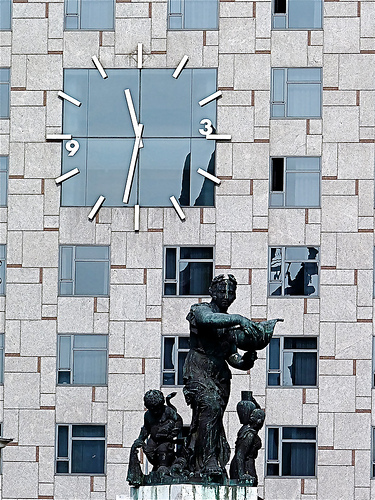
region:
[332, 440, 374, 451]
hotel catalonia, barcelona plaza, plaza espana, barcelona, spain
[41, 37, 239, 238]
the modern clock of the abovenoted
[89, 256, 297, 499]
statue is part of a fountain, & was designed by catalan architect, josep maria jujol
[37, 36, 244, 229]
clock is attached to a fancy hotel suite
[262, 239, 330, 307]
reflection of the statue in the mirrored windows of the fancy modernist hotel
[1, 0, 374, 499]
hotel is much MUCH larger than this, this is only a small detail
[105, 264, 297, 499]
tiny detail of an ENORMOUS almost crazily postmodern rococo fountain & statue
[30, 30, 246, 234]
clock is INCREDIBLY LARGE as well, 10'x10', easy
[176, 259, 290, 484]
woman with bowl needs to spend some time away from low flying birds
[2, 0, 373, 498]
the mosaicized walls of this hotel, in toto, continue for at least a block, more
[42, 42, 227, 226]
the fancy clock on the wall of the building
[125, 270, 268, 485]
the statue on top of the tower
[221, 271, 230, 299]
the white stain on the statue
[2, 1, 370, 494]
the building that the clock is attached too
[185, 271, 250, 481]
the part of the statue that looks like a woman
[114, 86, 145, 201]
the hands on the clock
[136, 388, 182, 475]
the statue that looks like a young boy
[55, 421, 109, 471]
a window of the building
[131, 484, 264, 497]
the base of the statue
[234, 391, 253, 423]
a vase on the statue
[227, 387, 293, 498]
This is a portrait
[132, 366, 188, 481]
This is a portrait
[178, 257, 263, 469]
This is a portrait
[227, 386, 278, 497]
This is a portrait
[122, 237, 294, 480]
sculpture is beside the building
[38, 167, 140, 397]
the building has more windows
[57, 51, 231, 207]
the building has a sketched wall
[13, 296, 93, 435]
the building is white in color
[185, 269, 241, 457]
sculpture of a man holding a bowel in hand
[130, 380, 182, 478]
sculpture of a person seated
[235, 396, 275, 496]
sculputre of a young person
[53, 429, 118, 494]
window panes are white in color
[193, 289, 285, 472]
sculpture are in blue color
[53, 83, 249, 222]
clock srick are white in color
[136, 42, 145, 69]
white line on clock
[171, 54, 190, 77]
white line on clock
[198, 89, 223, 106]
white line on clock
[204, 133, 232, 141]
white line on clock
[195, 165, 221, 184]
white line on clock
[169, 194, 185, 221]
white line on clock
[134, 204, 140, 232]
white line on clock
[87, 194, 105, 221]
white line on clock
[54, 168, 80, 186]
white line on clock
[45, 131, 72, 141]
white line on clock